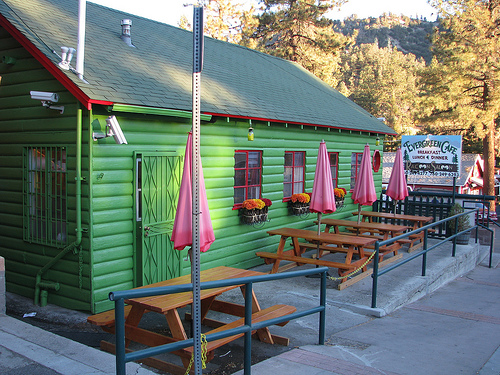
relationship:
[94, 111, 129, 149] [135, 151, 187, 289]
camera pointing towards door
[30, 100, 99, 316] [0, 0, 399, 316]
pipe on side of building